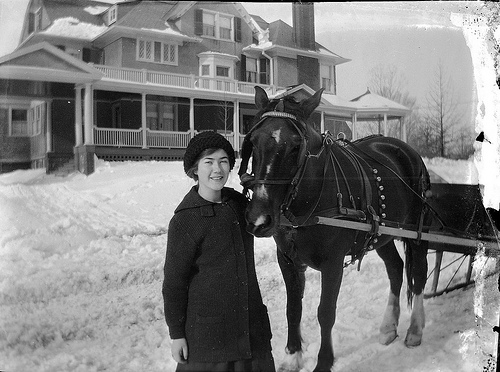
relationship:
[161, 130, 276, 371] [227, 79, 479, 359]
girl standing next to horse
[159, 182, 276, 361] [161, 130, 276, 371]
sweater on girl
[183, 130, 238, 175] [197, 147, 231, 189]
knit beanie on head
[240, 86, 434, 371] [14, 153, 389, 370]
horse standing in snow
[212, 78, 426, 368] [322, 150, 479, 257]
horse pulling sleigh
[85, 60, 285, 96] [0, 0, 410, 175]
balcony on house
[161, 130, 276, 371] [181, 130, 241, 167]
girl wearing hat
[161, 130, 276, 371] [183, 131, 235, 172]
girl in knit beanie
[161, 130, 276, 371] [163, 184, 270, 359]
girl in sweater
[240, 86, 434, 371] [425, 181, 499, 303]
horse pulling sleigh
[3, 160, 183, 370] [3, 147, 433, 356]
snow on lawn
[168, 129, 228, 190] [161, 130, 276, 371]
head of girl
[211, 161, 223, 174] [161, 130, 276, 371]
nose of girl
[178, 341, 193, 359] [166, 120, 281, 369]
thumb of woman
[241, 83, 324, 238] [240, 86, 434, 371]
head of horse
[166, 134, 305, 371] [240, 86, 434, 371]
girl beside horse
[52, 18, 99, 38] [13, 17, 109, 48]
snow on roof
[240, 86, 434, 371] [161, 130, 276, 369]
horse beside girl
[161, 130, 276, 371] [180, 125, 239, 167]
girl wearing hat